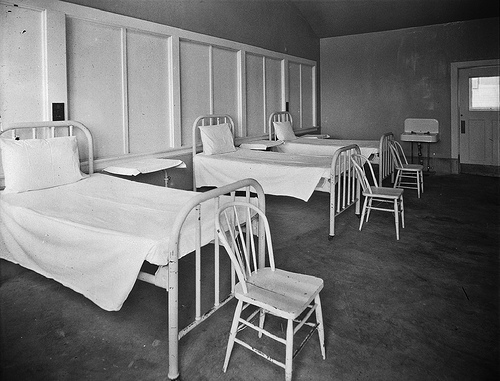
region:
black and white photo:
[68, 93, 403, 340]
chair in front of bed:
[196, 192, 352, 348]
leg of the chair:
[271, 322, 308, 379]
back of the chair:
[211, 193, 286, 291]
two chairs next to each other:
[342, 141, 427, 228]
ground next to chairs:
[343, 254, 428, 338]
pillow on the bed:
[9, 113, 111, 207]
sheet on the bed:
[60, 180, 147, 261]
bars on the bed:
[319, 136, 366, 211]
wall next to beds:
[343, 46, 425, 104]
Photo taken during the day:
[14, 18, 486, 368]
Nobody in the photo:
[22, 12, 479, 375]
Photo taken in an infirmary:
[11, 27, 491, 374]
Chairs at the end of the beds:
[231, 150, 415, 355]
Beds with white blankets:
[7, 128, 393, 293]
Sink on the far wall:
[397, 115, 449, 175]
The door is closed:
[446, 69, 498, 175]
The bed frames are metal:
[41, 129, 383, 325]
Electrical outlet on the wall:
[48, 97, 74, 129]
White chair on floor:
[207, 197, 352, 379]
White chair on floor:
[344, 144, 424, 246]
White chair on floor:
[376, 129, 454, 212]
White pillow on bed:
[3, 126, 96, 194]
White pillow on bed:
[193, 115, 239, 155]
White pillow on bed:
[262, 111, 290, 143]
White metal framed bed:
[0, 106, 274, 367]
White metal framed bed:
[183, 88, 379, 247]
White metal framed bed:
[253, 78, 408, 183]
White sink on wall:
[395, 91, 437, 188]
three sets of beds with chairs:
[7, 110, 422, 379]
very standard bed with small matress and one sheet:
[2, 168, 261, 310]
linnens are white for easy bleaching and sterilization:
[1, 133, 266, 310]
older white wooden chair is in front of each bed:
[211, 201, 328, 378]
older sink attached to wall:
[401, 116, 441, 180]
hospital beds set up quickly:
[2, 108, 419, 380]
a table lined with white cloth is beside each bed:
[102, 151, 187, 184]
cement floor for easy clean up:
[1, 170, 498, 377]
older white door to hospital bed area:
[447, 61, 498, 181]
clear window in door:
[465, 76, 498, 107]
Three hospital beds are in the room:
[12, 64, 404, 341]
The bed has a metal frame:
[2, 115, 275, 370]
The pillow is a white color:
[2, 134, 83, 189]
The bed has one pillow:
[3, 130, 90, 204]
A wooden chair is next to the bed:
[197, 192, 332, 379]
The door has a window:
[460, 66, 497, 112]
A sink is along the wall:
[393, 105, 443, 167]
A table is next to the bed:
[107, 150, 189, 182]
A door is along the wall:
[448, 58, 498, 175]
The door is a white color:
[447, 54, 498, 175]